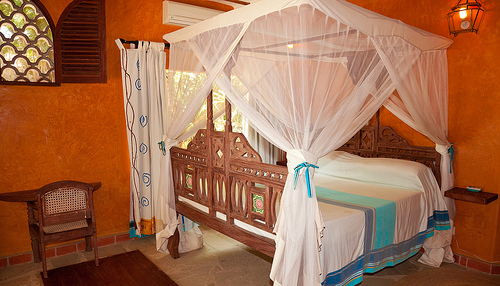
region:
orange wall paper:
[15, 98, 108, 153]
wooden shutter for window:
[54, 0, 109, 85]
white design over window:
[0, 0, 55, 82]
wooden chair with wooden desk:
[2, 181, 104, 268]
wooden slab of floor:
[106, 254, 158, 284]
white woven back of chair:
[44, 189, 86, 211]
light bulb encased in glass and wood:
[446, 0, 488, 36]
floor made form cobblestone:
[373, 271, 405, 279]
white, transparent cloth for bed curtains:
[166, 22, 328, 283]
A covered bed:
[157, 2, 457, 285]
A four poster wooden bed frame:
[158, 3, 450, 283]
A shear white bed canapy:
[154, 1, 456, 283]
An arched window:
[0, 1, 58, 86]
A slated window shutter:
[57, 1, 108, 84]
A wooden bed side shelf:
[444, 183, 496, 205]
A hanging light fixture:
[446, 2, 486, 36]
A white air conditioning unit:
[160, 1, 228, 27]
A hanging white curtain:
[114, 36, 172, 240]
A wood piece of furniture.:
[0, 174, 103, 276]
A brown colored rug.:
[41, 247, 180, 284]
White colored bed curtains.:
[157, 0, 455, 284]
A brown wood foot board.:
[166, 88, 288, 257]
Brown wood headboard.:
[333, 108, 441, 193]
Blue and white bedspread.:
[307, 150, 452, 285]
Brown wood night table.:
[442, 184, 499, 205]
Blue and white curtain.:
[113, 38, 166, 240]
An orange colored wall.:
[0, 0, 186, 256]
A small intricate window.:
[0, 0, 60, 87]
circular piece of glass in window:
[26, 67, 42, 82]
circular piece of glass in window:
[1, 68, 16, 80]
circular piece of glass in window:
[39, 56, 51, 75]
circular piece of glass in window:
[12, 56, 28, 73]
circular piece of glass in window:
[26, 46, 40, 63]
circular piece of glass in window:
[1, 43, 16, 65]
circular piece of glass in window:
[36, 37, 48, 52]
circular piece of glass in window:
[11, 33, 27, 53]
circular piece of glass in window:
[23, 3, 38, 20]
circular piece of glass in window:
[10, 10, 26, 30]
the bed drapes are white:
[180, 7, 444, 264]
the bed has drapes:
[60, 10, 482, 281]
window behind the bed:
[153, 67, 254, 145]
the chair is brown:
[17, 172, 107, 259]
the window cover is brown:
[56, 5, 116, 84]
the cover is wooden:
[63, 2, 108, 71]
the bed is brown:
[133, 150, 313, 232]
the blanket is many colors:
[299, 178, 409, 252]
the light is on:
[457, 3, 482, 44]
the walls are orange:
[15, 17, 152, 199]